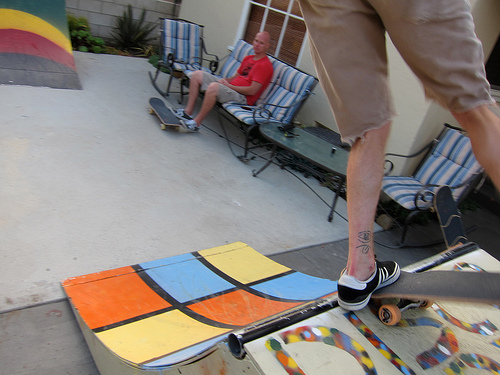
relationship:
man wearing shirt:
[167, 21, 277, 133] [224, 53, 275, 112]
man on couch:
[167, 21, 277, 133] [181, 36, 318, 179]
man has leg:
[295, 0, 498, 313] [305, 14, 406, 309]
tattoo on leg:
[355, 225, 375, 258] [305, 14, 406, 309]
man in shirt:
[167, 21, 277, 133] [224, 53, 275, 112]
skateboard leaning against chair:
[422, 182, 475, 249] [381, 116, 495, 251]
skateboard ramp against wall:
[1, 1, 86, 94] [66, 0, 180, 61]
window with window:
[242, 0, 308, 67] [242, 0, 308, 67]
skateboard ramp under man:
[52, 238, 337, 369] [295, 0, 498, 313]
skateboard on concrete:
[146, 95, 186, 138] [0, 45, 386, 312]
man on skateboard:
[295, 0, 498, 313] [371, 260, 499, 323]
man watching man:
[167, 21, 277, 133] [295, 0, 498, 313]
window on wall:
[242, 0, 308, 67] [175, 0, 499, 196]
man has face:
[167, 21, 277, 133] [252, 35, 270, 52]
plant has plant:
[66, 12, 110, 58] [66, 12, 110, 58]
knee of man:
[204, 82, 223, 102] [167, 21, 277, 133]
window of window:
[242, 0, 308, 67] [242, 0, 308, 67]